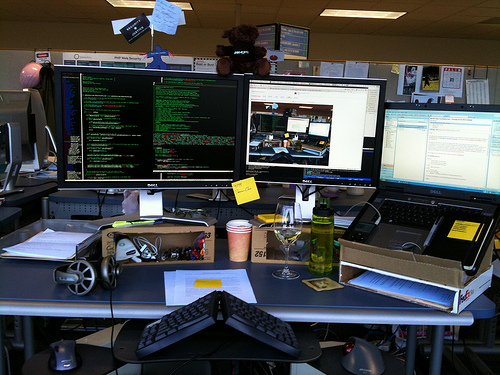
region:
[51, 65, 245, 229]
a black computer monitor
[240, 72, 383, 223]
a black computer monitor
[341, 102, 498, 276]
an open laptop computer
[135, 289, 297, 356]
a black split keyboard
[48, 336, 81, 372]
a black and grey computer mouse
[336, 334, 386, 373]
a grey and red trackball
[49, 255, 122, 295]
a pair of headsets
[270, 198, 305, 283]
a glass of wine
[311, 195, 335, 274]
a bottle of wine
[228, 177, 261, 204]
a yellow sticky note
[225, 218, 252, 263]
Three stacked paper cups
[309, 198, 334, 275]
Green plastic water bottle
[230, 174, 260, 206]
Writing on a yellow sticky note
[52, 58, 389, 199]
Two black computer screens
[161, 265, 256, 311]
Two pieces of paper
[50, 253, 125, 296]
Large silver headphones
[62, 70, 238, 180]
Computer code on a wide screen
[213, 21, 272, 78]
Dark brown teddy bear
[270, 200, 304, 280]
White wine in a wine glass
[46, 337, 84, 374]
Black and gray computer mouse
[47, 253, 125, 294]
headphone on top of table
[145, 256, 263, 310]
paper on top of table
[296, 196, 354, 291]
bottle on top of table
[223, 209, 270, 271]
cup on top of table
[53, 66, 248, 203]
monitor on top of table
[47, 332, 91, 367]
mouse on top of table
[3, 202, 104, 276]
paper on top of table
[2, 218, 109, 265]
tray on top of table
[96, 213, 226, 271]
stand on top of table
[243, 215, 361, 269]
stand on top of table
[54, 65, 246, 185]
computer monitor with debugging information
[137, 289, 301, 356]
black folding keyboard on the desk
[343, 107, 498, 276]
open laptop perched on a box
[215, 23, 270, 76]
dark brown teddy bear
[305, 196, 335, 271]
reusable water bottle on a desk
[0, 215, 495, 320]
office desk with various items on top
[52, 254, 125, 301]
over ear headphones on desk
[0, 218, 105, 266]
paper bin filled with loose paper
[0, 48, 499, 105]
office board with various papers posted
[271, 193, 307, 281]
wine glass with a small amount of liquid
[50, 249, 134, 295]
Large head phones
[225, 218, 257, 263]
A stack of empty coffee cups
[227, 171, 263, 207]
A yellow sticky with writing on it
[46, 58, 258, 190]
An open computer screen with green writing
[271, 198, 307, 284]
An empty wine glass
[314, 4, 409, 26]
Lit ceiling lights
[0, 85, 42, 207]
The back of a computer screen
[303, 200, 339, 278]
Yellow clear water bottle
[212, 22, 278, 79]
A brown teddy bear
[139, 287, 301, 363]
A folded key board